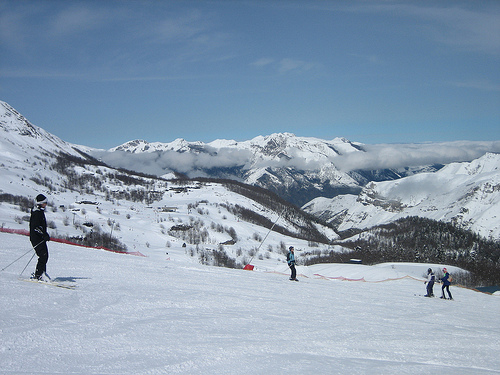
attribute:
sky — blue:
[282, 32, 400, 96]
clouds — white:
[171, 41, 480, 119]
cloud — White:
[8, 9, 98, 52]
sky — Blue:
[378, 29, 490, 134]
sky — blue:
[234, 37, 403, 109]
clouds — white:
[4, 5, 498, 52]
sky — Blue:
[2, 4, 498, 140]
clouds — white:
[42, 9, 484, 104]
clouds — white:
[4, 9, 484, 90]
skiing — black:
[28, 207, 49, 278]